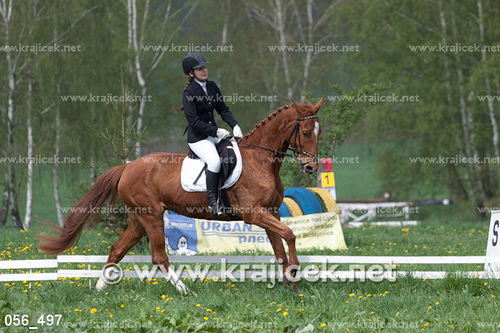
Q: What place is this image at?
A: It is at the field.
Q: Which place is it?
A: It is a field.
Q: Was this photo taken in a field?
A: Yes, it was taken in a field.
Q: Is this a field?
A: Yes, it is a field.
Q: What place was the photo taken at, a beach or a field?
A: It was taken at a field.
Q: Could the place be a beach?
A: No, it is a field.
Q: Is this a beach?
A: No, it is a field.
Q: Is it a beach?
A: No, it is a field.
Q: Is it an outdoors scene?
A: Yes, it is outdoors.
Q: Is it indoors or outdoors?
A: It is outdoors.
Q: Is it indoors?
A: No, it is outdoors.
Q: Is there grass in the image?
A: Yes, there is grass.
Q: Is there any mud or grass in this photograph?
A: Yes, there is grass.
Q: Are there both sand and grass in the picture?
A: No, there is grass but no sand.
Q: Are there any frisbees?
A: No, there are no frisbees.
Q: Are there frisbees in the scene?
A: No, there are no frisbees.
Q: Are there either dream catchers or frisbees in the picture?
A: No, there are no frisbees or dream catchers.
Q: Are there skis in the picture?
A: No, there are no skis.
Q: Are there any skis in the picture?
A: No, there are no skis.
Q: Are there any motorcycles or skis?
A: No, there are no skis or motorcycles.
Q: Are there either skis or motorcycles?
A: No, there are no skis or motorcycles.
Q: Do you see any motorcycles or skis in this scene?
A: No, there are no skis or motorcycles.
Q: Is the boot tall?
A: Yes, the boot is tall.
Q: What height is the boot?
A: The boot is tall.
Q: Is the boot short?
A: No, the boot is tall.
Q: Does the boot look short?
A: No, the boot is tall.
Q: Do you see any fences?
A: Yes, there is a fence.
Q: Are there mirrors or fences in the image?
A: Yes, there is a fence.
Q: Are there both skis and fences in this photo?
A: No, there is a fence but no skis.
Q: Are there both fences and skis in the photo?
A: No, there is a fence but no skis.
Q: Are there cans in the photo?
A: No, there are no cans.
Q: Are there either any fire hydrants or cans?
A: No, there are no cans or fire hydrants.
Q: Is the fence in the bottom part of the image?
A: Yes, the fence is in the bottom of the image.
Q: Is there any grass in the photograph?
A: Yes, there is grass.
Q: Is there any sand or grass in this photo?
A: Yes, there is grass.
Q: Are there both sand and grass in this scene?
A: No, there is grass but no sand.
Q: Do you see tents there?
A: No, there are no tents.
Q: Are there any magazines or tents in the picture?
A: No, there are no tents or magazines.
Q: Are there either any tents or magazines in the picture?
A: No, there are no tents or magazines.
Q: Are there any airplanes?
A: No, there are no airplanes.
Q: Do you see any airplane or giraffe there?
A: No, there are no airplanes or giraffes.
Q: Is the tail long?
A: Yes, the tail is long.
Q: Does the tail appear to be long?
A: Yes, the tail is long.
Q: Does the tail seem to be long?
A: Yes, the tail is long.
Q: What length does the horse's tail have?
A: The tail has long length.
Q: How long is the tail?
A: The tail is long.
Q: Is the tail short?
A: No, the tail is long.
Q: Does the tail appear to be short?
A: No, the tail is long.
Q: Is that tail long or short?
A: The tail is long.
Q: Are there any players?
A: No, there are no players.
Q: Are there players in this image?
A: No, there are no players.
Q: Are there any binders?
A: No, there are no binders.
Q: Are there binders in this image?
A: No, there are no binders.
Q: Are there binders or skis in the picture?
A: No, there are no binders or skis.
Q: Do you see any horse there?
A: Yes, there is a horse.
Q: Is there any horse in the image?
A: Yes, there is a horse.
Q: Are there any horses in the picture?
A: Yes, there is a horse.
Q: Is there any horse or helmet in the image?
A: Yes, there is a horse.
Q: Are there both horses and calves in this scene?
A: No, there is a horse but no calves.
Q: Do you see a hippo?
A: No, there are no hippos.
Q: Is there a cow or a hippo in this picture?
A: No, there are no hippos or cows.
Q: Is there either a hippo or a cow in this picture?
A: No, there are no hippos or cows.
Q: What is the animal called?
A: The animal is a horse.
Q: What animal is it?
A: The animal is a horse.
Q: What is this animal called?
A: This is a horse.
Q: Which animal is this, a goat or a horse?
A: This is a horse.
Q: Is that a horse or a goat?
A: That is a horse.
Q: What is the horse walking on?
A: The horse is walking on the grass.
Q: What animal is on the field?
A: The horse is on the field.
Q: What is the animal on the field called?
A: The animal is a horse.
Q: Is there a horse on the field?
A: Yes, there is a horse on the field.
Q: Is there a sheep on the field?
A: No, there is a horse on the field.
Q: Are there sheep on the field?
A: No, there is a horse on the field.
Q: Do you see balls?
A: No, there are no balls.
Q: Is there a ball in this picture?
A: No, there are no balls.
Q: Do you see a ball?
A: No, there are no balls.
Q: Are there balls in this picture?
A: No, there are no balls.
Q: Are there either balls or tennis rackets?
A: No, there are no balls or tennis rackets.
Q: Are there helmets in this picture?
A: Yes, there is a helmet.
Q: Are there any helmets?
A: Yes, there is a helmet.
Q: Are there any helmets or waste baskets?
A: Yes, there is a helmet.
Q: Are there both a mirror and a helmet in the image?
A: No, there is a helmet but no mirrors.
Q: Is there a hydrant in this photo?
A: No, there are no fire hydrants.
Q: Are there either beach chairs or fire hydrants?
A: No, there are no fire hydrants or beach chairs.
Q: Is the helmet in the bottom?
A: No, the helmet is in the top of the image.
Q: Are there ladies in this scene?
A: No, there are no ladies.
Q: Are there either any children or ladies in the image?
A: No, there are no ladies or children.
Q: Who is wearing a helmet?
A: The jockey is wearing a helmet.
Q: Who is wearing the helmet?
A: The jockey is wearing a helmet.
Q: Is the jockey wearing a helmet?
A: Yes, the jockey is wearing a helmet.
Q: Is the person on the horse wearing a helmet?
A: Yes, the jockey is wearing a helmet.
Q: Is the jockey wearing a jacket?
A: No, the jockey is wearing a helmet.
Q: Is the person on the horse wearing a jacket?
A: No, the jockey is wearing a helmet.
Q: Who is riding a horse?
A: The jockey is riding a horse.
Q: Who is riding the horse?
A: The jockey is riding a horse.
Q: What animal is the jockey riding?
A: The jockey is riding a horse.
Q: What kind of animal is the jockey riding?
A: The jockey is riding a horse.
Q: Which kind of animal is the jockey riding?
A: The jockey is riding a horse.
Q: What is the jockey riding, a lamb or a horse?
A: The jockey is riding a horse.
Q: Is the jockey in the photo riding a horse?
A: Yes, the jockey is riding a horse.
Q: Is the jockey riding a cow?
A: No, the jockey is riding a horse.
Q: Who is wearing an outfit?
A: The jockey is wearing an outfit.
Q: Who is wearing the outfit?
A: The jockey is wearing an outfit.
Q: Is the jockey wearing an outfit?
A: Yes, the jockey is wearing an outfit.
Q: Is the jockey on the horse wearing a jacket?
A: No, the jockey is wearing an outfit.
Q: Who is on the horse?
A: The jockey is on the horse.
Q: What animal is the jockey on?
A: The jockey is on the horse.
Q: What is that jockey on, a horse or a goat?
A: The jockey is on a horse.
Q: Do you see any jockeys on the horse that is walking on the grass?
A: Yes, there is a jockey on the horse.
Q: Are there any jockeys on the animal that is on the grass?
A: Yes, there is a jockey on the horse.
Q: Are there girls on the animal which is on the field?
A: No, there is a jockey on the horse.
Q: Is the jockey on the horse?
A: Yes, the jockey is on the horse.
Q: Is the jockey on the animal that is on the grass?
A: Yes, the jockey is on the horse.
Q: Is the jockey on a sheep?
A: No, the jockey is on the horse.